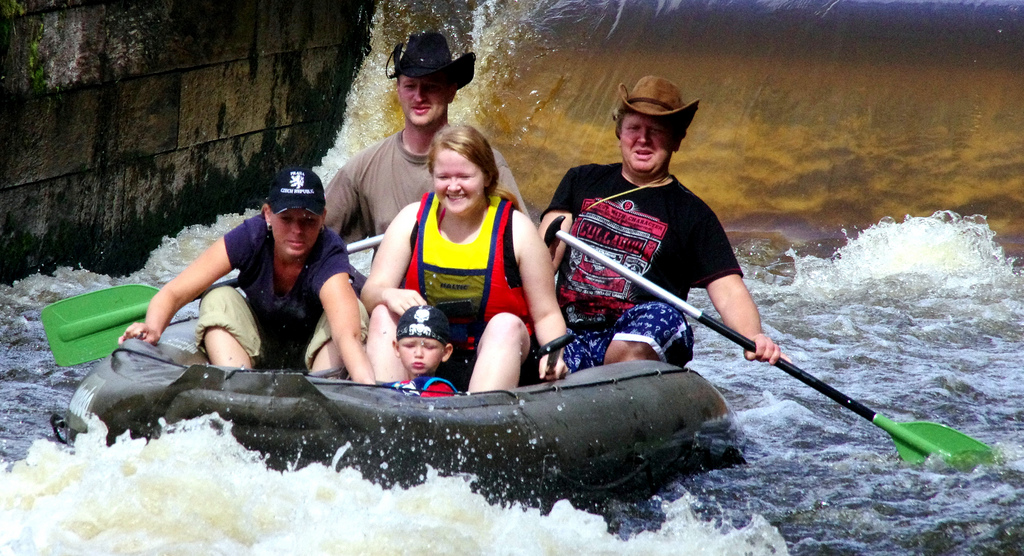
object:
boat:
[46, 309, 756, 502]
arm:
[312, 269, 380, 386]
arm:
[118, 236, 228, 342]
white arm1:
[506, 209, 571, 356]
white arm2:
[362, 197, 419, 306]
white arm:
[710, 272, 753, 333]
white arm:
[544, 209, 571, 266]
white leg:
[198, 313, 256, 372]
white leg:
[307, 337, 334, 370]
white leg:
[365, 299, 401, 386]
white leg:
[468, 312, 529, 393]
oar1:
[27, 249, 199, 373]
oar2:
[544, 224, 985, 463]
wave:
[13, 430, 586, 552]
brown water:
[732, 8, 1013, 214]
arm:
[510, 208, 565, 379]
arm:
[358, 199, 427, 321]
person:
[137, 163, 369, 386]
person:
[353, 128, 570, 388]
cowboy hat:
[379, 26, 485, 86]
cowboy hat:
[602, 70, 703, 121]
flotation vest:
[403, 186, 525, 328]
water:
[732, 442, 916, 552]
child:
[395, 306, 462, 402]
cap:
[400, 306, 454, 345]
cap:
[273, 164, 328, 210]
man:
[545, 82, 773, 372]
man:
[323, 43, 512, 238]